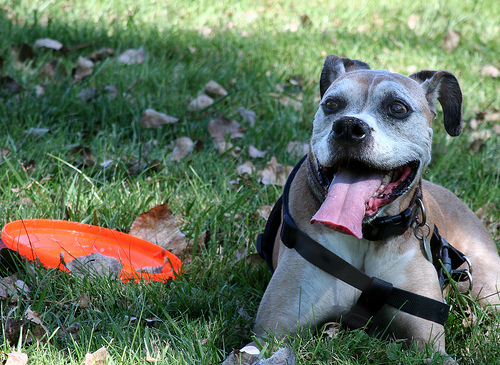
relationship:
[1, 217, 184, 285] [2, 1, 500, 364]
frisbee in grass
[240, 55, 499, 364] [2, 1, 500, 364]
dog on grass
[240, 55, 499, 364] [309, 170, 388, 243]
dog has tongue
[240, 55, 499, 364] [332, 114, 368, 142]
dog has nose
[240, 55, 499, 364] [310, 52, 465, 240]
dog has head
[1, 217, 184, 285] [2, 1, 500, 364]
frisbee on grass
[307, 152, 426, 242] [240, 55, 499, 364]
collar on dog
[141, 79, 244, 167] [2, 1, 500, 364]
leaves on grass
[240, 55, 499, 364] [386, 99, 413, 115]
dog has eye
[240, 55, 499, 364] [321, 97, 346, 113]
dog has eye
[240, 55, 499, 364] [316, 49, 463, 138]
dog has ears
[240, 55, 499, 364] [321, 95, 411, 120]
dog has eyes